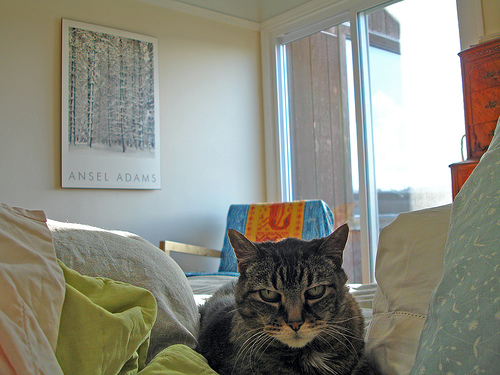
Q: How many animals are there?
A: One.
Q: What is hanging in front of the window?
A: Blinds.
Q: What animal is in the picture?
A: A cat.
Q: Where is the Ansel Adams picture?
A: On the wall.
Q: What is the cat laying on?
A: A bed.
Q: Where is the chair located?
A: In front of the window.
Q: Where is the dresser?
A: Right side of window.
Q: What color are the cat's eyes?
A: Green.